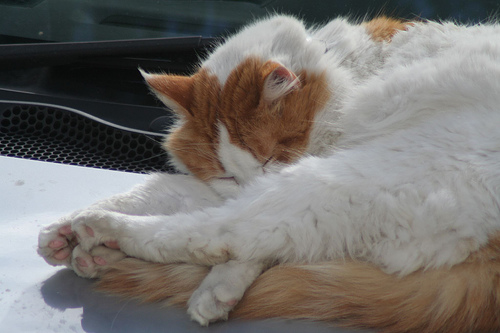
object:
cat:
[37, 13, 500, 332]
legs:
[72, 156, 404, 264]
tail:
[93, 241, 500, 331]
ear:
[135, 66, 196, 122]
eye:
[262, 153, 277, 167]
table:
[1, 144, 378, 332]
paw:
[36, 221, 77, 266]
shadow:
[40, 266, 385, 332]